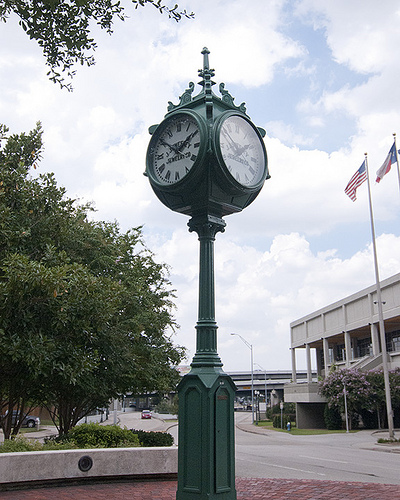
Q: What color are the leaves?
A: Green.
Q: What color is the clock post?
A: Green.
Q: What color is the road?
A: Grey.